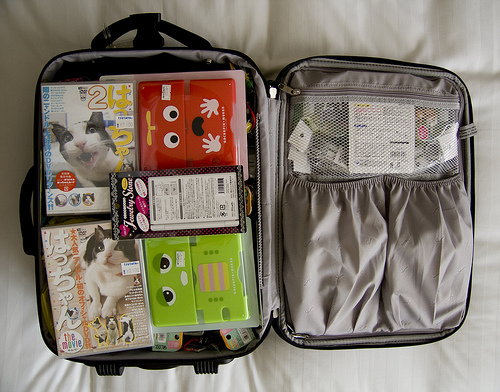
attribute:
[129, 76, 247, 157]
dvd — orange 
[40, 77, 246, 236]
case — DVD  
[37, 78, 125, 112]
number — 2   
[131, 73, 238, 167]
toy — red, surprised looking  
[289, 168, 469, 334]
pocket — mesh 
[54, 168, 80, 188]
tag — orange , green 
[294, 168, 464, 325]
pockets — brown 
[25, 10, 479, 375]
suitcase — side , bottom , small open , open black 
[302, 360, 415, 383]
sheet — white 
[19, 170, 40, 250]
handle — black 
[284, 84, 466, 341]
compartment — mesh  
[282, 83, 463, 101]
zipper — gray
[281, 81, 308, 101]
zipper — silver, metal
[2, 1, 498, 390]
sheets — white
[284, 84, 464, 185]
mesh net — full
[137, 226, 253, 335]
case — green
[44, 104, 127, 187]
cat — black, white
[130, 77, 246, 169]
case — red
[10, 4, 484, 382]
luggage — stuffed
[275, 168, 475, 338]
pouch — gray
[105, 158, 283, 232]
cards — white, black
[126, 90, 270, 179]
holder — red, silly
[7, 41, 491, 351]
pack — gray, holding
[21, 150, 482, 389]
pack — open, gray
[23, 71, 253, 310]
objects — assorted, bundled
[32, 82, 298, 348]
items — small, pink, green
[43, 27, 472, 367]
bag — black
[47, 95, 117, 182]
cat — gray, white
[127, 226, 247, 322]
package — green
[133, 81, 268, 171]
package — red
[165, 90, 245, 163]
package — white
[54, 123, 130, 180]
mouth — open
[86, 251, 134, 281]
mouth — closed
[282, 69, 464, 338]
lining — gray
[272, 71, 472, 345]
lining — grey